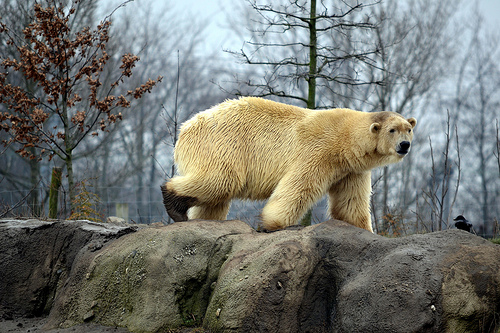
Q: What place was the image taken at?
A: It was taken at the forest.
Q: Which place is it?
A: It is a forest.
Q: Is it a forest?
A: Yes, it is a forest.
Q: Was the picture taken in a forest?
A: Yes, it was taken in a forest.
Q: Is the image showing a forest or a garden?
A: It is showing a forest.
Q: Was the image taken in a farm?
A: No, the picture was taken in a forest.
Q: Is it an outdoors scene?
A: Yes, it is outdoors.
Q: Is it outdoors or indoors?
A: It is outdoors.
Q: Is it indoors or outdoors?
A: It is outdoors.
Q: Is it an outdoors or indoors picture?
A: It is outdoors.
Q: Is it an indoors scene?
A: No, it is outdoors.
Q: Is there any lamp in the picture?
A: No, there are no lamps.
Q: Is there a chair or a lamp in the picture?
A: No, there are no lamps or chairs.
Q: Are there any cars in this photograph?
A: No, there are no cars.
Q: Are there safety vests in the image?
A: No, there are no safety vests.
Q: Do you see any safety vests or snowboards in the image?
A: No, there are no safety vests or snowboards.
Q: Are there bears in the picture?
A: Yes, there is a bear.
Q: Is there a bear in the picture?
A: Yes, there is a bear.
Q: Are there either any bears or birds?
A: Yes, there is a bear.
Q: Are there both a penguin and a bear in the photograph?
A: No, there is a bear but no penguins.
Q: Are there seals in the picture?
A: No, there are no seals.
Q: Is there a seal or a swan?
A: No, there are no seals or swans.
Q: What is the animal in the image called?
A: The animal is a bear.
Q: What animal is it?
A: The animal is a bear.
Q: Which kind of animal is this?
A: This is a bear.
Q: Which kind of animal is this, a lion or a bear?
A: This is a bear.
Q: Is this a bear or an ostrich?
A: This is a bear.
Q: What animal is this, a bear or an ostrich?
A: This is a bear.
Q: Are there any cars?
A: No, there are no cars.